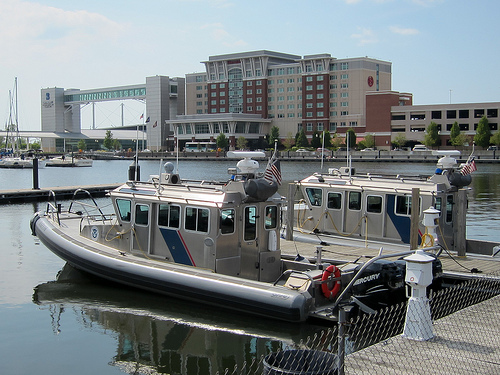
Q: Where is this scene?
A: Harbor.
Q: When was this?
A: Daytime.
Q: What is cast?
A: Reflection.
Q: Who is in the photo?
A: No one.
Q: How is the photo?
A: Clear.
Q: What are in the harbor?
A: Boats.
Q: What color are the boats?
A: White.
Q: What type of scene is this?
A: Outdoor.